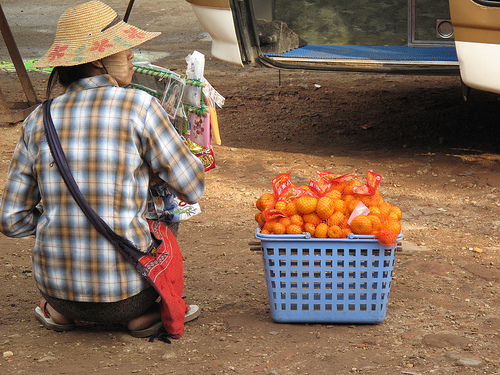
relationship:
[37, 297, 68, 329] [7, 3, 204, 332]
foot of woman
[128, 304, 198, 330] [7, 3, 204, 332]
foot of woman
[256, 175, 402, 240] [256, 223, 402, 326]
oranges in basket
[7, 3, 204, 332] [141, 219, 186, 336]
woman wearing bag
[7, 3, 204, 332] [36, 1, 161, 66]
woman wearing hat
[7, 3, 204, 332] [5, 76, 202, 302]
woman wearing shirt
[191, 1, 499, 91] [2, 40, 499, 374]
van on ground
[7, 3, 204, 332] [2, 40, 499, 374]
woman on ground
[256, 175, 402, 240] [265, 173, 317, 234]
oranges in bag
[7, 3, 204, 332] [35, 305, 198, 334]
woman wearing flip-flops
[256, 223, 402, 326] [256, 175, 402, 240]
basket of oranges